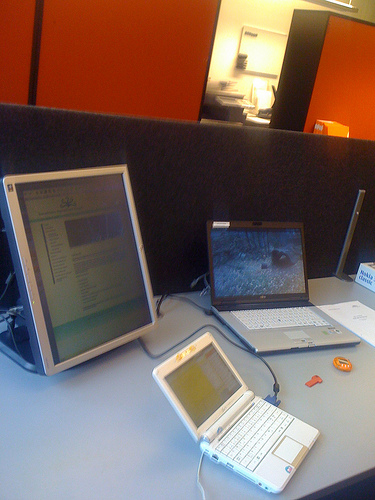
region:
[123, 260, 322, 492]
a computer on a table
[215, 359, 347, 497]
a computer on a table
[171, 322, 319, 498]
small plastic white laptop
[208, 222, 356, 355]
silver and black laptop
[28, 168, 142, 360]
square silver computer monitor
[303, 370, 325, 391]
orange plastic dongle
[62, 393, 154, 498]
flat white table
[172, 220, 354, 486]
two laptops on desk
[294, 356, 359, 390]
two plastic orange dongles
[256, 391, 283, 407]
blue vga adapter connected to laptop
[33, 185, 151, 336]
web page open on the monitor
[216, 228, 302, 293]
desktop background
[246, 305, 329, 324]
white keyboard on laptop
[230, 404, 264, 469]
white keyboard on laptop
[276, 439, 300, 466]
white trackpad on laptop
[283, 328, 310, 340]
silver trackpad on laptop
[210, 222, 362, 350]
black and silver laptop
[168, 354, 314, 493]
small white laptop on table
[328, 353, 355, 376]
orange electronic object on table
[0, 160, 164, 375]
tall silver computer monitor on table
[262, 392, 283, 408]
blue dongle in computer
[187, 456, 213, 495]
white computer cable in laptop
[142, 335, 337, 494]
VERY SMALL LAPTOP COMPUTER OPENED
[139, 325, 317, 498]
VERY SMALL LAPTOP COMPUTER TURNED ON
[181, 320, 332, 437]
COMPUTER CORD CONNECTED TO VERY SMALL LAPTOP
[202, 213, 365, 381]
STANDARD SIZED LAPTOP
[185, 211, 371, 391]
STANDARD SIZED LAPTOP OPENED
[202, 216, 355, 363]
STANDARD SIZED LAPTOP TURNED ON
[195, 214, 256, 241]
LABEL ON THE STANDARD SIZED LAPTOP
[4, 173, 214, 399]
STAND ALONE COMPUTER SCREEN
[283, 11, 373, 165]
ORANGE PAINTED WALL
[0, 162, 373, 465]
THREE DIFFERENT COMPUTER SCREENS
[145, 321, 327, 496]
a white computer